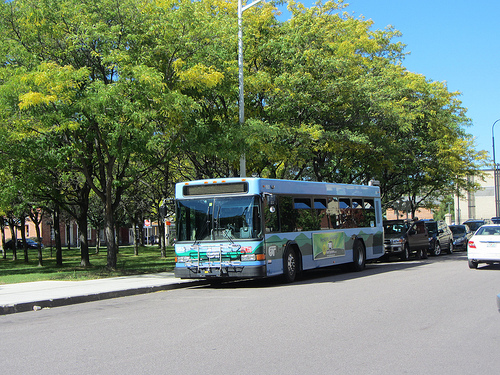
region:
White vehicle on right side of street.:
[466, 217, 498, 274]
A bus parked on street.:
[169, 152, 392, 290]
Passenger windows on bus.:
[283, 188, 383, 233]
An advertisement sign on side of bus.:
[308, 230, 349, 259]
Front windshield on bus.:
[169, 197, 265, 246]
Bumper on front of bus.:
[171, 260, 267, 282]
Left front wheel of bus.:
[280, 238, 307, 283]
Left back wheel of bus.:
[342, 232, 372, 274]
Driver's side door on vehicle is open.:
[383, 210, 438, 263]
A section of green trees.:
[11, 12, 450, 279]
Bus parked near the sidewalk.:
[149, 163, 399, 275]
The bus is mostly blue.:
[147, 166, 398, 282]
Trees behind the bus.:
[0, 23, 457, 236]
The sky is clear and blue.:
[233, 0, 498, 181]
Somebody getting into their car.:
[407, 208, 430, 264]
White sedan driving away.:
[457, 216, 498, 278]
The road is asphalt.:
[24, 268, 496, 370]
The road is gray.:
[4, 251, 498, 369]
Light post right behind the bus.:
[228, 0, 260, 195]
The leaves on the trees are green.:
[14, 0, 487, 219]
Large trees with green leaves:
[0, 0, 165, 265]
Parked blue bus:
[170, 175, 385, 280]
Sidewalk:
[0, 275, 170, 310]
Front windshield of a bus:
[174, 198, 257, 239]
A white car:
[465, 220, 495, 265]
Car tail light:
[465, 235, 475, 245]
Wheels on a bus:
[280, 240, 300, 275]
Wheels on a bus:
[350, 235, 365, 270]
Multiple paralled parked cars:
[380, 215, 495, 265]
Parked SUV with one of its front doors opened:
[385, 215, 425, 255]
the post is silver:
[202, 5, 282, 180]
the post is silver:
[197, 7, 301, 276]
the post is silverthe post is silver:
[210, 4, 278, 221]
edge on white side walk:
[49, 294, 96, 305]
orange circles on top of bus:
[170, 171, 262, 185]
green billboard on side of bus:
[306, 223, 369, 264]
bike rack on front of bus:
[186, 232, 249, 289]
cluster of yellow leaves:
[20, 76, 76, 126]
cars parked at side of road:
[388, 212, 465, 254]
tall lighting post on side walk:
[233, 5, 250, 148]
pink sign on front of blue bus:
[233, 238, 261, 258]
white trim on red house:
[47, 212, 89, 252]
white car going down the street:
[451, 205, 486, 280]